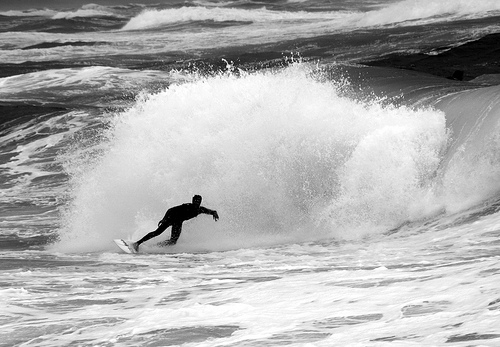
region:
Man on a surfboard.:
[108, 164, 311, 268]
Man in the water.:
[103, 158, 313, 287]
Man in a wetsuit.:
[66, 157, 229, 274]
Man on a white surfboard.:
[94, 181, 221, 251]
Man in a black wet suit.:
[108, 159, 254, 318]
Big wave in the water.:
[65, 36, 474, 346]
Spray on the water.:
[98, 54, 444, 169]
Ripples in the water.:
[122, 229, 345, 342]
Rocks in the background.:
[375, 30, 486, 71]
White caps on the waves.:
[76, 277, 295, 326]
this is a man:
[141, 183, 220, 242]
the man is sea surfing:
[131, 187, 221, 251]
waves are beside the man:
[263, 63, 403, 189]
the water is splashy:
[221, 77, 319, 192]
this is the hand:
[198, 204, 222, 224]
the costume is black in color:
[169, 205, 196, 220]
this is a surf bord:
[112, 234, 137, 251]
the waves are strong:
[258, 60, 454, 160]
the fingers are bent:
[212, 210, 219, 220]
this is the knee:
[165, 232, 182, 247]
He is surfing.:
[104, 178, 234, 265]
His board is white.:
[100, 217, 127, 252]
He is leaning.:
[113, 174, 206, 265]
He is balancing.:
[98, 183, 213, 288]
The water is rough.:
[10, 9, 486, 344]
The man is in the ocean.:
[8, 11, 498, 338]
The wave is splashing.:
[27, 28, 479, 344]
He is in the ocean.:
[6, 2, 496, 342]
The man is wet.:
[95, 169, 238, 272]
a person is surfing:
[84, 160, 326, 295]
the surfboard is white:
[93, 199, 173, 281]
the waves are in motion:
[62, 32, 445, 278]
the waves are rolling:
[274, 17, 491, 299]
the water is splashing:
[60, 106, 352, 273]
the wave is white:
[70, 53, 429, 336]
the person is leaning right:
[102, 185, 235, 283]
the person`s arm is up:
[160, 171, 237, 267]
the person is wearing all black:
[120, 183, 233, 257]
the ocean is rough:
[12, 1, 443, 268]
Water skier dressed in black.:
[134, 193, 224, 255]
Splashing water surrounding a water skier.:
[68, 71, 452, 246]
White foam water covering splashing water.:
[178, 281, 495, 333]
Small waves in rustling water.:
[16, 91, 124, 108]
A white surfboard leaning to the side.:
[115, 235, 138, 256]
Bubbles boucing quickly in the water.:
[172, 28, 321, 38]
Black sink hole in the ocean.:
[408, 40, 498, 89]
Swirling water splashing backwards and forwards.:
[39, 20, 467, 185]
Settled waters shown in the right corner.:
[414, 303, 498, 333]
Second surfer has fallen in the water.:
[447, 65, 468, 77]